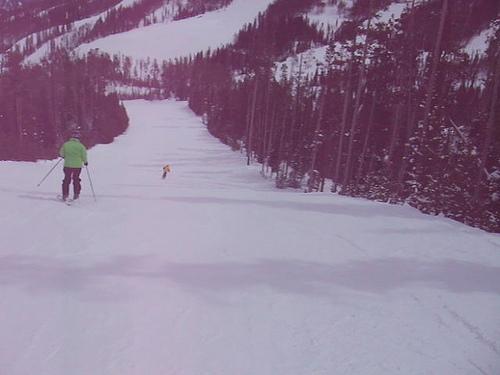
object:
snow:
[179, 173, 291, 290]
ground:
[204, 176, 251, 291]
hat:
[71, 130, 81, 137]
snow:
[0, 288, 196, 374]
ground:
[298, 207, 390, 246]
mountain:
[0, 3, 498, 373]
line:
[470, 33, 499, 218]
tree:
[414, 0, 449, 224]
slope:
[1, 97, 498, 373]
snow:
[185, 201, 349, 292]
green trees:
[2, 56, 132, 170]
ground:
[6, 260, 253, 372]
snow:
[388, 268, 478, 361]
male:
[58, 130, 88, 202]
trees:
[249, 0, 351, 189]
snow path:
[0, 95, 498, 371]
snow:
[332, 260, 364, 291]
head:
[71, 129, 81, 141]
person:
[161, 164, 170, 180]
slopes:
[105, 100, 387, 357]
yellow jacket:
[163, 165, 171, 173]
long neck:
[281, 56, 386, 188]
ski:
[55, 194, 81, 206]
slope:
[102, 164, 289, 280]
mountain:
[104, 0, 309, 146]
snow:
[23, 213, 160, 345]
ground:
[4, 160, 443, 264]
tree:
[352, 3, 426, 191]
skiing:
[24, 126, 121, 210]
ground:
[172, 194, 294, 278]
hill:
[231, 1, 499, 124]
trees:
[157, 52, 201, 105]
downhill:
[1, 96, 388, 211]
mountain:
[0, 0, 300, 103]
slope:
[95, 155, 447, 373]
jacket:
[59, 137, 87, 168]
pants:
[61, 167, 81, 201]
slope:
[110, 96, 220, 188]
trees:
[225, 41, 297, 161]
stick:
[85, 165, 97, 201]